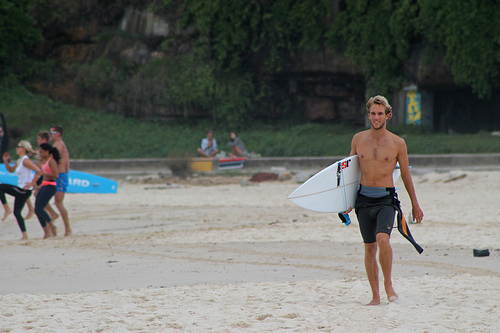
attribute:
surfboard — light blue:
[0, 158, 120, 198]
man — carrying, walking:
[347, 94, 417, 307]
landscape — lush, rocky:
[0, 5, 476, 156]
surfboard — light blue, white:
[1, 155, 121, 196]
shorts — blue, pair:
[52, 170, 69, 194]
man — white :
[338, 86, 428, 311]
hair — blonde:
[363, 89, 398, 131]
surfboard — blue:
[2, 158, 118, 195]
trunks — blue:
[50, 171, 70, 193]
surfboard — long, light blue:
[27, 148, 138, 217]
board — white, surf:
[281, 156, 419, 213]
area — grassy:
[150, 147, 297, 165]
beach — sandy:
[170, 266, 486, 330]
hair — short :
[364, 93, 387, 105]